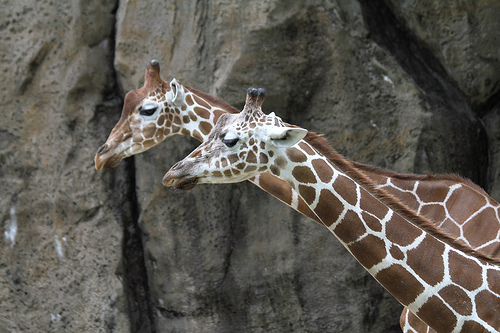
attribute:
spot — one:
[382, 240, 420, 264]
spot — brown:
[439, 283, 471, 325]